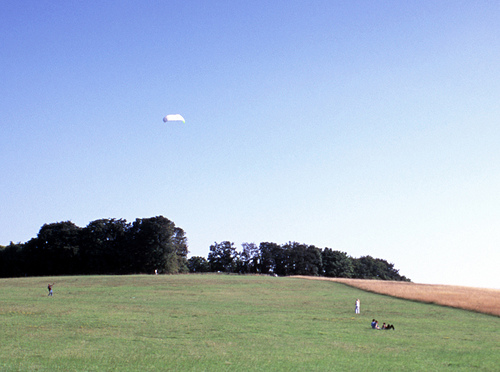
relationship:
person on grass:
[351, 293, 367, 316] [327, 313, 361, 341]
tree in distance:
[31, 228, 273, 270] [19, 168, 405, 302]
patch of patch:
[425, 273, 457, 286] [283, 273, 500, 316]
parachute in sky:
[160, 114, 185, 124] [0, 0, 499, 290]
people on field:
[339, 307, 407, 354] [288, 269, 417, 370]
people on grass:
[339, 307, 407, 354] [327, 313, 361, 341]